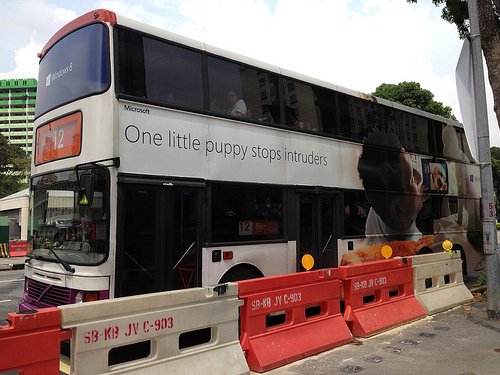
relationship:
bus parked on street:
[17, 8, 482, 355] [4, 278, 22, 303]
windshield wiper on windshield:
[42, 239, 87, 272] [27, 169, 112, 266]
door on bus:
[295, 184, 341, 269] [15, 6, 478, 321]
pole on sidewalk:
[466, 1, 499, 320] [248, 295, 498, 373]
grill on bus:
[21, 282, 71, 307] [29, 21, 481, 351]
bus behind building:
[15, 6, 478, 321] [2, 77, 32, 162]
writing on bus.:
[121, 123, 333, 171] [28, 8, 415, 274]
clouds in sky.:
[1, 0, 497, 147] [222, 4, 422, 72]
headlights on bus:
[72, 291, 83, 303] [15, 6, 478, 321]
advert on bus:
[106, 91, 488, 210] [35, 34, 442, 291]